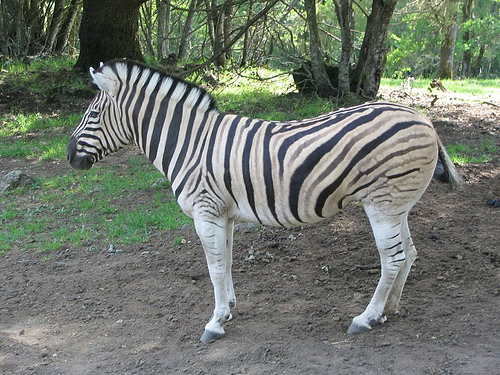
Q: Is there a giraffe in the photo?
A: No, there are no giraffes.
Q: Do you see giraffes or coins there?
A: No, there are no giraffes or coins.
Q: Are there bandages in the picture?
A: No, there are no bandages.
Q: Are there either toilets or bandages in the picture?
A: No, there are no bandages or toilets.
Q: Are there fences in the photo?
A: No, there are no fences.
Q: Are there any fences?
A: No, there are no fences.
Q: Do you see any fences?
A: No, there are no fences.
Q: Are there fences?
A: No, there are no fences.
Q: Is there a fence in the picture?
A: No, there are no fences.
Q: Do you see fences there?
A: No, there are no fences.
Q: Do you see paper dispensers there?
A: No, there are no paper dispensers.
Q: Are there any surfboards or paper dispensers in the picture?
A: No, there are no paper dispensers or surfboards.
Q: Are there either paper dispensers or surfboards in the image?
A: No, there are no paper dispensers or surfboards.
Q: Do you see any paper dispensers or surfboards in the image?
A: No, there are no paper dispensers or surfboards.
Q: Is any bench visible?
A: No, there are no benches.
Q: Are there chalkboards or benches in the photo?
A: No, there are no benches or chalkboards.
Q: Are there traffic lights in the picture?
A: No, there are no traffic lights.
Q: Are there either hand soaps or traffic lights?
A: No, there are no traffic lights or hand soaps.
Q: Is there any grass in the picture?
A: Yes, there is grass.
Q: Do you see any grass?
A: Yes, there is grass.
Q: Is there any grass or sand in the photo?
A: Yes, there is grass.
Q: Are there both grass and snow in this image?
A: No, there is grass but no snow.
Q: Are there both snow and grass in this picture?
A: No, there is grass but no snow.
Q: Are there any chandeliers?
A: No, there are no chandeliers.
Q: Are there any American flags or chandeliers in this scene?
A: No, there are no chandeliers or American flags.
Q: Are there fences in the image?
A: No, there are no fences.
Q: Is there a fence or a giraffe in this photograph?
A: No, there are no fences or giraffes.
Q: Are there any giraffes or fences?
A: No, there are no fences or giraffes.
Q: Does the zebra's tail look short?
A: Yes, the tail is short.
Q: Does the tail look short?
A: Yes, the tail is short.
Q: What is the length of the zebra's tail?
A: The tail is short.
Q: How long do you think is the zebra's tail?
A: The tail is short.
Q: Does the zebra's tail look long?
A: No, the tail is short.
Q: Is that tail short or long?
A: The tail is short.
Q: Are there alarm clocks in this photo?
A: No, there are no alarm clocks.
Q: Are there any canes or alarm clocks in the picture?
A: No, there are no alarm clocks or canes.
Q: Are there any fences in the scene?
A: No, there are no fences.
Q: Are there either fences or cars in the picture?
A: No, there are no fences or cars.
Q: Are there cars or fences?
A: No, there are no fences or cars.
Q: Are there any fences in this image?
A: No, there are no fences.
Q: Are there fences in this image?
A: No, there are no fences.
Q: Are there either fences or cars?
A: No, there are no fences or cars.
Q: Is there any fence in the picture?
A: No, there are no fences.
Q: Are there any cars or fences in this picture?
A: No, there are no fences or cars.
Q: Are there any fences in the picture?
A: No, there are no fences.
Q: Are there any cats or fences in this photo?
A: No, there are no fences or cats.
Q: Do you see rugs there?
A: No, there are no rugs.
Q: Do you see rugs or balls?
A: No, there are no rugs or balls.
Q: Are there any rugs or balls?
A: No, there are no rugs or balls.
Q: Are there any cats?
A: No, there are no cats.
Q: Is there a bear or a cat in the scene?
A: No, there are no cats or bears.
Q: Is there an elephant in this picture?
A: No, there are no elephants.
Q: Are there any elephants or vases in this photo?
A: No, there are no elephants or vases.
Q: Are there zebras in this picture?
A: Yes, there is a zebra.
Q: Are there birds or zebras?
A: Yes, there is a zebra.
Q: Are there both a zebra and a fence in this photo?
A: No, there is a zebra but no fences.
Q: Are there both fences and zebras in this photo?
A: No, there is a zebra but no fences.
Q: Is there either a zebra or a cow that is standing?
A: Yes, the zebra is standing.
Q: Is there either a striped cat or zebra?
A: Yes, there is a striped zebra.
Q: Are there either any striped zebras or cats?
A: Yes, there is a striped zebra.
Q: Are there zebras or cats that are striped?
A: Yes, the zebra is striped.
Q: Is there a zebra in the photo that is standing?
A: Yes, there is a zebra that is standing.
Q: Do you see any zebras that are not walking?
A: Yes, there is a zebra that is standing .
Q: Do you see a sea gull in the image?
A: No, there are no seagulls.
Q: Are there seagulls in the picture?
A: No, there are no seagulls.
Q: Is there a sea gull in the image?
A: No, there are no seagulls.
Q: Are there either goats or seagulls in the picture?
A: No, there are no seagulls or goats.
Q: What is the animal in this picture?
A: The animal is a zebra.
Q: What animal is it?
A: The animal is a zebra.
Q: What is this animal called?
A: That is a zebra.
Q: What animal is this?
A: That is a zebra.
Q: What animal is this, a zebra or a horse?
A: That is a zebra.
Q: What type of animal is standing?
A: The animal is a zebra.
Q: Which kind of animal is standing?
A: The animal is a zebra.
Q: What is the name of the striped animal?
A: The animal is a zebra.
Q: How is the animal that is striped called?
A: The animal is a zebra.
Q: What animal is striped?
A: The animal is a zebra.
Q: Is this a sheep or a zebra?
A: This is a zebra.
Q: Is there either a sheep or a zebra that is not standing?
A: No, there is a zebra but it is standing.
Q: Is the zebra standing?
A: Yes, the zebra is standing.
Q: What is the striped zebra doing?
A: The zebra is standing.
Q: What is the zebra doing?
A: The zebra is standing.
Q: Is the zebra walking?
A: No, the zebra is standing.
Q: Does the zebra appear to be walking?
A: No, the zebra is standing.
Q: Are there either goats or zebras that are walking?
A: No, there is a zebra but it is standing.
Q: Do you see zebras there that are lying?
A: No, there is a zebra but it is standing.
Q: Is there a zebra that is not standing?
A: No, there is a zebra but it is standing.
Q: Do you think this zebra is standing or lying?
A: The zebra is standing.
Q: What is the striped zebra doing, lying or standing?
A: The zebra is standing.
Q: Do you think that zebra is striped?
A: Yes, the zebra is striped.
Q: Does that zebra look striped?
A: Yes, the zebra is striped.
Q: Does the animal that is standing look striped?
A: Yes, the zebra is striped.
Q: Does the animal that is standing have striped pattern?
A: Yes, the zebra is striped.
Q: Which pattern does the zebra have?
A: The zebra has striped pattern.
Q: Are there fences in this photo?
A: No, there are no fences.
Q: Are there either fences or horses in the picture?
A: No, there are no fences or horses.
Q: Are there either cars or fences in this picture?
A: No, there are no fences or cars.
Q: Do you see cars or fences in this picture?
A: No, there are no fences or cars.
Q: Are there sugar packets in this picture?
A: No, there are no sugar packets.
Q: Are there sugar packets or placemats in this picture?
A: No, there are no sugar packets or placemats.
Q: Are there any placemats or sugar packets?
A: No, there are no sugar packets or placemats.